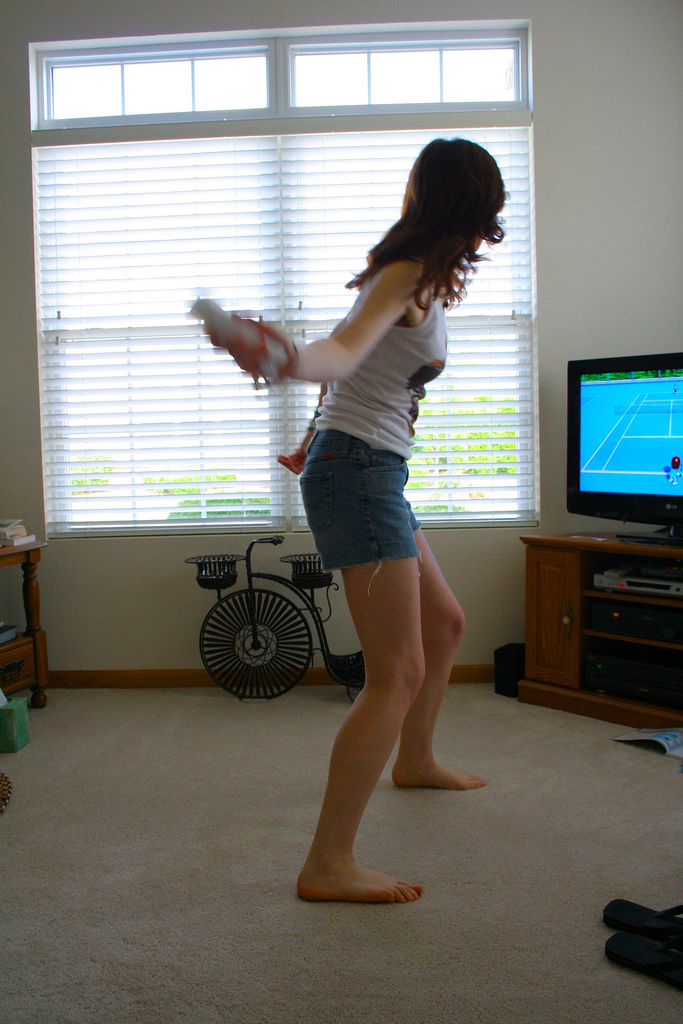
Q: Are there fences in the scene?
A: No, there are no fences.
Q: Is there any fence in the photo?
A: No, there are no fences.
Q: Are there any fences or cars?
A: No, there are no fences or cars.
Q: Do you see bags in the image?
A: No, there are no bags.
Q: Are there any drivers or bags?
A: No, there are no bags or drivers.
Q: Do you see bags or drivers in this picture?
A: No, there are no bags or drivers.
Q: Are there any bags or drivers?
A: No, there are no bags or drivers.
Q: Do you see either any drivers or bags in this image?
A: No, there are no bags or drivers.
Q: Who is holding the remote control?
A: The lady is holding the remote control.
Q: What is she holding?
A: The lady is holding the remote.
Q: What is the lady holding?
A: The lady is holding the remote.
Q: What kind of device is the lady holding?
A: The lady is holding the remote control.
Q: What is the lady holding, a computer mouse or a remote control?
A: The lady is holding a remote control.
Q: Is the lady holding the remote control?
A: Yes, the lady is holding the remote control.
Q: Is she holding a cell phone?
A: No, the lady is holding the remote control.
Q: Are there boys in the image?
A: No, there are no boys.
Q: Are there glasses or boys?
A: No, there are no boys or glasses.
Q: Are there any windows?
A: Yes, there is a window.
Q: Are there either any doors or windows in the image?
A: Yes, there is a window.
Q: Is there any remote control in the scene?
A: Yes, there is a remote control.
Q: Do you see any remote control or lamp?
A: Yes, there is a remote control.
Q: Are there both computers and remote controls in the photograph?
A: No, there is a remote control but no computers.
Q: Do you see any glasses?
A: No, there are no glasses.